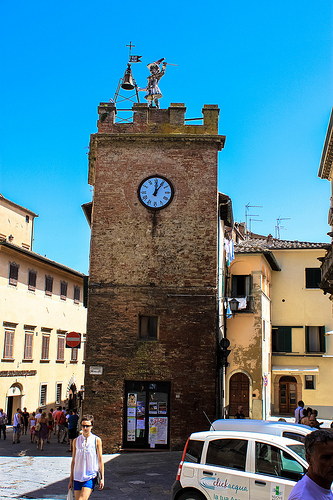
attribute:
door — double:
[122, 379, 170, 450]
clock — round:
[126, 164, 190, 212]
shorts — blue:
[73, 468, 94, 489]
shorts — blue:
[73, 476, 91, 490]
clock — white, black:
[136, 172, 175, 211]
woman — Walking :
[33, 410, 52, 450]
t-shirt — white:
[286, 474, 330, 499]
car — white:
[172, 433, 314, 496]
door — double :
[148, 380, 169, 449]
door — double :
[122, 380, 146, 448]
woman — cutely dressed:
[64, 415, 110, 497]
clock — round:
[139, 176, 172, 213]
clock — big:
[135, 175, 174, 209]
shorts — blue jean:
[71, 476, 95, 491]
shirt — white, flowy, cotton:
[73, 431, 98, 481]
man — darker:
[289, 430, 331, 498]